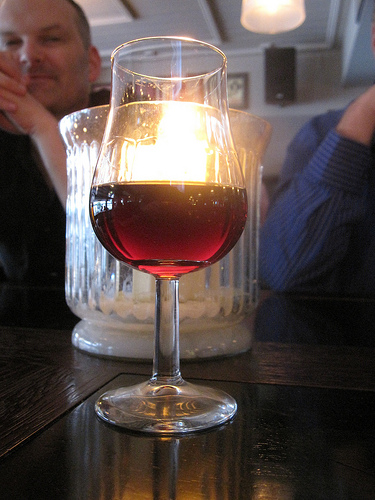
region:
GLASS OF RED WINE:
[107, 48, 230, 260]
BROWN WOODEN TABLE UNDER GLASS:
[8, 333, 333, 498]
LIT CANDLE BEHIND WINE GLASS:
[123, 100, 232, 185]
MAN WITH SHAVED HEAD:
[1, 1, 100, 140]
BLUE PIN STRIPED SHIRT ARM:
[255, 74, 373, 287]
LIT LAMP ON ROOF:
[235, 1, 287, 40]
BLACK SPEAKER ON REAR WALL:
[254, 46, 303, 104]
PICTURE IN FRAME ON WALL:
[227, 73, 247, 107]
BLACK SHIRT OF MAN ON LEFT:
[3, 133, 68, 303]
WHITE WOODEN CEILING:
[45, 14, 327, 54]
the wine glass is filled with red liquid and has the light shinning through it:
[88, 32, 250, 427]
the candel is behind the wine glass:
[57, 98, 272, 357]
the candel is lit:
[57, 96, 275, 363]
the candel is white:
[54, 98, 276, 362]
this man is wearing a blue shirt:
[263, 74, 374, 291]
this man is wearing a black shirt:
[3, 0, 127, 325]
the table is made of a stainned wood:
[5, 285, 373, 497]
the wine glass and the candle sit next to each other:
[54, 34, 277, 440]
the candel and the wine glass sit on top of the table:
[58, 33, 280, 434]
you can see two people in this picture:
[1, 0, 374, 315]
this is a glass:
[120, 70, 202, 164]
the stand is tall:
[117, 286, 217, 428]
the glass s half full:
[124, 192, 217, 248]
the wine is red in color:
[105, 191, 223, 255]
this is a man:
[1, 6, 84, 105]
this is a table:
[262, 382, 350, 497]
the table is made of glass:
[253, 405, 339, 495]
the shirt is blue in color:
[282, 139, 354, 278]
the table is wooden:
[290, 351, 333, 383]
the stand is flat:
[106, 366, 221, 445]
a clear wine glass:
[72, 31, 267, 443]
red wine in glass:
[91, 38, 252, 287]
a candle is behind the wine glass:
[53, 26, 276, 472]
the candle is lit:
[40, 62, 278, 370]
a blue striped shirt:
[261, 96, 368, 310]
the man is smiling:
[0, 0, 124, 144]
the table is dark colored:
[3, 289, 374, 494]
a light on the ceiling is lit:
[229, 0, 336, 57]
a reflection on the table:
[39, 426, 307, 496]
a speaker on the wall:
[253, 36, 318, 117]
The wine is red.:
[122, 196, 210, 247]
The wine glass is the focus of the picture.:
[84, 26, 252, 448]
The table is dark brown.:
[240, 425, 357, 495]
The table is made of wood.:
[235, 427, 362, 498]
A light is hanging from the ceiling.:
[233, 0, 325, 41]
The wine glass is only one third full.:
[77, 34, 260, 284]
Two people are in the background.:
[0, 0, 373, 309]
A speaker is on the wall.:
[249, 39, 309, 110]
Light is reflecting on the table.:
[111, 462, 234, 496]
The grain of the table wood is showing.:
[4, 355, 65, 423]